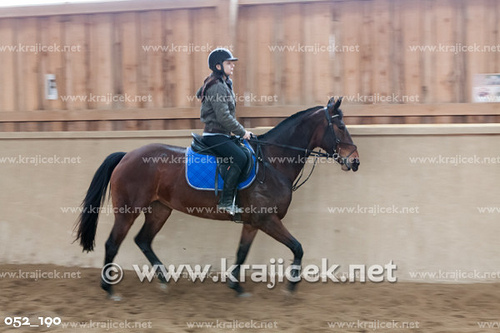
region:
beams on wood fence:
[4, 3, 498, 125]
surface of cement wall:
[3, 125, 497, 280]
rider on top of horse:
[75, 48, 358, 296]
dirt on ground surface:
[1, 265, 494, 331]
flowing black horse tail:
[74, 151, 124, 251]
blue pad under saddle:
[184, 135, 264, 191]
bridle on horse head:
[318, 103, 356, 165]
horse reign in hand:
[238, 135, 329, 182]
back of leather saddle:
[188, 131, 211, 153]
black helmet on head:
[210, 48, 237, 73]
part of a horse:
[283, 229, 304, 267]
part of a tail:
[158, 199, 170, 248]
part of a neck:
[299, 133, 308, 148]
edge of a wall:
[181, 260, 195, 282]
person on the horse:
[49, 19, 377, 266]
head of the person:
[189, 32, 262, 95]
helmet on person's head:
[192, 32, 245, 88]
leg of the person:
[201, 119, 254, 226]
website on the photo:
[123, 243, 433, 297]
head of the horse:
[296, 80, 386, 188]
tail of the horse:
[38, 140, 138, 277]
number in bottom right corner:
[3, 299, 39, 331]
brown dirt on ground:
[296, 284, 403, 324]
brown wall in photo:
[71, 30, 146, 95]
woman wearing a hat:
[183, 37, 270, 232]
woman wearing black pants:
[205, 35, 265, 211]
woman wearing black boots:
[195, 42, 255, 227]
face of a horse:
[320, 91, 380, 181]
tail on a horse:
[65, 140, 121, 275]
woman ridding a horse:
[190, 37, 260, 227]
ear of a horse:
[333, 95, 354, 116]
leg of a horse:
[270, 230, 301, 300]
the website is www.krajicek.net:
[113, 244, 404, 331]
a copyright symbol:
[75, 252, 132, 289]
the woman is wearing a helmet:
[192, 40, 254, 91]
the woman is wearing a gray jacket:
[149, 26, 269, 220]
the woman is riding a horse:
[134, 24, 404, 236]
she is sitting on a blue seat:
[166, 96, 268, 213]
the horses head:
[265, 72, 393, 181]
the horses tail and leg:
[60, 121, 130, 297]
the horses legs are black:
[96, 213, 318, 300]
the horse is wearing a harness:
[292, 80, 402, 193]